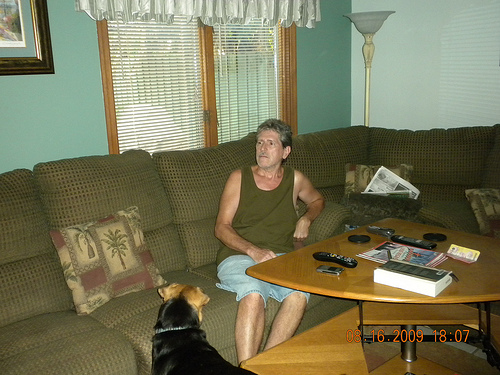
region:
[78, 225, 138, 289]
a pillow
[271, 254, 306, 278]
a table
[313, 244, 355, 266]
controller on the table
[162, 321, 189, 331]
collar on the dog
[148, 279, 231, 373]
a dog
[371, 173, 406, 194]
a newspaper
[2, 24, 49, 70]
a picture on the wall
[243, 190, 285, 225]
man is wearing a brown shirt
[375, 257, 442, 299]
a book on the table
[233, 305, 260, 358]
the mans leg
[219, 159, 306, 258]
man is wearing tank top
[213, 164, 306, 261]
man's tank top is green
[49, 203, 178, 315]
palm trees on the pillow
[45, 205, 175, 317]
pillow is brown and red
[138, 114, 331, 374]
dog is looking at man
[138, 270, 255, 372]
dog is brown and black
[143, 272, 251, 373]
dog is wearing a collar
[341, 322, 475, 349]
orange numbers on picture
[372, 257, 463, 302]
book laying on the table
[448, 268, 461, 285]
bookmark in the book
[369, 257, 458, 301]
book lying on coffee table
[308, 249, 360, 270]
black remote control sitting on coffee table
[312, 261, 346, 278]
cell phone sitting on coffee table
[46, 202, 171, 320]
throw pillow sitting on couch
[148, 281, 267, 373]
black and brown dog standing in front of couch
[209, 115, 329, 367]
man in tank top sitting on couch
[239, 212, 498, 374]
large coffee table sitting in front of couch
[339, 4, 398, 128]
floor lamp sitting behind couch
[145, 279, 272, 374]
black and brown dog looking at man on couch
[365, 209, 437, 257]
remote controls sitting on coffee table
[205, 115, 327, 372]
man is sitting on sectional couch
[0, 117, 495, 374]
large brown sectional couch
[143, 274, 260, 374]
brown and black dog is next to man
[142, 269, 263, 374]
black dog has brown head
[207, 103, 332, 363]
man is wearing a green tank top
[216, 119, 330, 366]
man is wearing denim shorts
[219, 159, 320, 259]
green tank top on man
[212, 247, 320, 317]
denim shorts on man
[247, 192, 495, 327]
wedge shaped table in front of man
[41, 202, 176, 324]
tropical themed pillow on couch next to man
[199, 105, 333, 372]
a man sitting on a couch.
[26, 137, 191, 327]
a pillow on a couch.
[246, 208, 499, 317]
a wooden coffee table.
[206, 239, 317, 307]
a pair of blue shorts.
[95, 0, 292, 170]
a window behind a couch.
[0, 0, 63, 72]
a picture framed on a wall.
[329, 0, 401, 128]
a lamp behind a couch.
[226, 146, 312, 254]
a brown tank top.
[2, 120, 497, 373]
a large brown couch.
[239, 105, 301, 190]
a man with short hair.